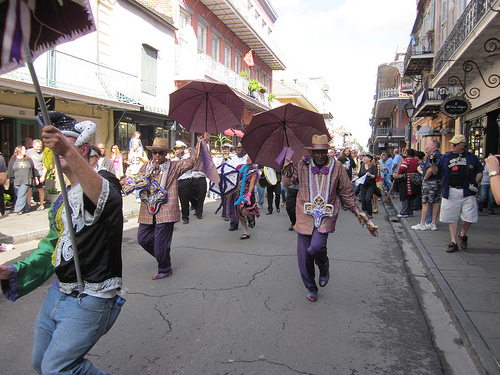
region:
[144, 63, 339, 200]
men carrying umbrellas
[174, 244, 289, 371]
cracks in the road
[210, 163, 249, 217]
blue and white umbrella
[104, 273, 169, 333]
water bottle in man's back pocket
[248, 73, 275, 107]
plants on the balcony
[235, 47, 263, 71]
a red and white flag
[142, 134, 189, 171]
man is wearing sunglasses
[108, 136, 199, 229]
man playing an instrument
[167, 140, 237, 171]
members of a band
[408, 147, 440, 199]
man has his hand in his pocket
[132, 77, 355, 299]
Two men holding umbrellas in the street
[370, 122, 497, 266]
People observing on the sidewalk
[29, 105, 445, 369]
A parade going through the empty street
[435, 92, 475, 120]
The sign of a shop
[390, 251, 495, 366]
The curb between the sidewalk and the street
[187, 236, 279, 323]
Cracks in the street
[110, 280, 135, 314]
A water bottle in the back pocket of jeans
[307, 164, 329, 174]
A purple bowtie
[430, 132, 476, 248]
A man wearing white shorts watching the crowd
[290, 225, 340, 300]
A pair of purple pants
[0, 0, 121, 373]
Man walking in parade with a flag.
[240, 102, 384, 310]
Man walking in a parade with a pink umbrella.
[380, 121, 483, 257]
People watching a parade.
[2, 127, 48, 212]
People leaving a business.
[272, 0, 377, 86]
Blue and white sky.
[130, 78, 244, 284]
Man dancing in parade with umbrella.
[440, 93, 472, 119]
Sign for a business.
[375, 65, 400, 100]
Balcony on a building.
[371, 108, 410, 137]
Balcony of a building.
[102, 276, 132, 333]
Water bottle in a man's pocket.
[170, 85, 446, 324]
umbrella is very visible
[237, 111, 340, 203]
umbrella is very visible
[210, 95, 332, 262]
umbrella is very visible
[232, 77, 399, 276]
umbrella is very visible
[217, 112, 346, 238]
an umbrella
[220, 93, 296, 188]
an umbrella